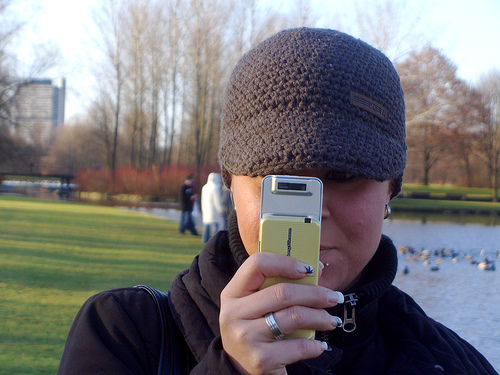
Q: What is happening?
A: The woman is taking a picture.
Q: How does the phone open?
A: The mobile phone slides apart.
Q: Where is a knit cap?
A: On woman's head.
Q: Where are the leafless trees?
A: Other side of water.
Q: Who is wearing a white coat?
A: Person behind woman with phone.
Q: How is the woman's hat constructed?
A: Knit.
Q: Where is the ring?
A: Woman's ring finger of her right hand.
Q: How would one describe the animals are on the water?
A: Ducks.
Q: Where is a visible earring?
A: Woman's left ear.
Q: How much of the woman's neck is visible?
A: None, the coat blocks the view.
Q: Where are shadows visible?
A: On the grass.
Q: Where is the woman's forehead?
A: Hidden behind the bill of her cap.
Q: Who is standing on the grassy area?
A: A group of people.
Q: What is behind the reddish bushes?
A: Tall thin trees.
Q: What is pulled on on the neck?
A: A black jacket with collar.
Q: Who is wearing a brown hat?
A: A woman.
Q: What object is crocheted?
A: A brown hat.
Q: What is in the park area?
A: A pond.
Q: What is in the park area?
A: Grass.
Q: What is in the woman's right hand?
A: A cell phone.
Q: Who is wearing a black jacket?
A: A woman.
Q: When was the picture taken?
A: Daytime.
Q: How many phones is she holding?
A: One.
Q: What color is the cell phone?
A: Yellow and Silver.